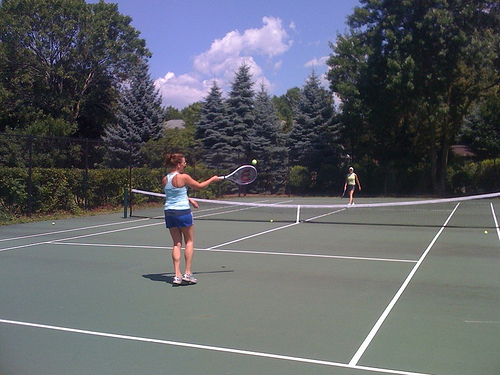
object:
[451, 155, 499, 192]
trimmed hedges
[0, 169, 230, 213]
trimmed hedges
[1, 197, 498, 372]
tennis court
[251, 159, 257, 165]
ball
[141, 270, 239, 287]
shadow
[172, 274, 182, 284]
foot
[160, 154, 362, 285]
people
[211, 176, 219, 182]
hand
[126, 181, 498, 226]
fence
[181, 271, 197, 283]
foot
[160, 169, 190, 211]
top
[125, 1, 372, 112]
sky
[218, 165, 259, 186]
racket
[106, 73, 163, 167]
trees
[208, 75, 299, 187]
trees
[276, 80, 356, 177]
trees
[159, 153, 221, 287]
person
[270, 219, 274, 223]
tennis ball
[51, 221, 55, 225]
tennis ball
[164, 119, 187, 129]
roof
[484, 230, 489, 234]
ball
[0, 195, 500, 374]
court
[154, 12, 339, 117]
cloud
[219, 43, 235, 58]
part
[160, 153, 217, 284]
girls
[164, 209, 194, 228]
short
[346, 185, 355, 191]
shorts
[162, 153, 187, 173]
head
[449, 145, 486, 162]
building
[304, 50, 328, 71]
part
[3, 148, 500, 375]
game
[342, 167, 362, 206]
person